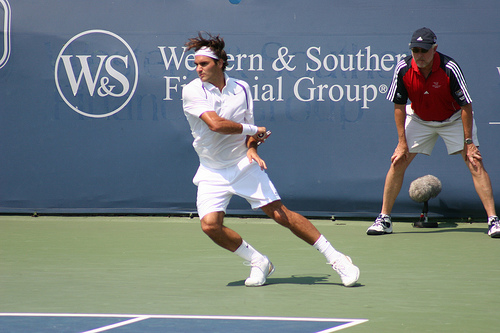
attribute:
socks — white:
[316, 236, 338, 263]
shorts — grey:
[395, 96, 479, 158]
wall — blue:
[28, 86, 205, 200]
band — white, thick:
[189, 45, 229, 64]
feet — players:
[266, 201, 406, 301]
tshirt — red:
[388, 62, 481, 139]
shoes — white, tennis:
[333, 248, 360, 287]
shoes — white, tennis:
[244, 246, 270, 295]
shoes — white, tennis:
[366, 210, 394, 233]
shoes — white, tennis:
[482, 218, 498, 233]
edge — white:
[331, 308, 367, 327]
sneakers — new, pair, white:
[243, 253, 367, 295]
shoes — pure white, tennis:
[235, 254, 362, 291]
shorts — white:
[180, 162, 261, 209]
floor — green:
[311, 275, 471, 331]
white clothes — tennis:
[179, 74, 281, 221]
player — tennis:
[181, 35, 361, 288]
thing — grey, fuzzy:
[407, 172, 459, 227]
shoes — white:
[366, 210, 499, 239]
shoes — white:
[244, 255, 362, 290]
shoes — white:
[329, 254, 362, 288]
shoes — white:
[242, 254, 274, 287]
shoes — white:
[365, 213, 393, 235]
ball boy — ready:
[360, 20, 498, 234]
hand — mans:
[448, 140, 495, 177]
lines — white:
[13, 308, 402, 329]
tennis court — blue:
[4, 215, 482, 329]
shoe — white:
[483, 213, 499, 238]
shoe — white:
[364, 214, 389, 232]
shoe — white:
[330, 253, 363, 285]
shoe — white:
[240, 254, 272, 286]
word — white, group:
[290, 73, 379, 111]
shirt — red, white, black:
[408, 41, 459, 95]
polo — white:
[169, 77, 273, 172]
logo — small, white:
[413, 34, 425, 42]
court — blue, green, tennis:
[3, 221, 489, 326]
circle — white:
[50, 27, 139, 118]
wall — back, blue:
[0, 0, 496, 219]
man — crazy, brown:
[160, 25, 380, 295]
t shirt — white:
[176, 76, 264, 168]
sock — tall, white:
[316, 227, 352, 270]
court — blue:
[6, 319, 374, 332]